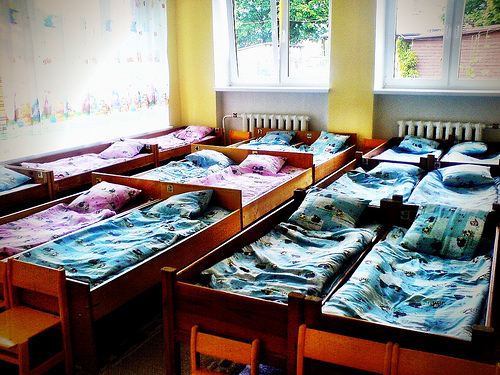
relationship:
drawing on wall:
[13, 99, 41, 130] [1, 1, 172, 163]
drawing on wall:
[41, 13, 58, 29] [1, 1, 172, 163]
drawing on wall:
[142, 88, 169, 109] [1, 1, 172, 163]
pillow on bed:
[172, 124, 216, 141] [130, 124, 224, 166]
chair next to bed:
[1, 256, 75, 375] [1, 181, 242, 371]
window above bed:
[221, 1, 330, 89] [130, 124, 224, 166]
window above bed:
[221, 1, 330, 89] [191, 127, 300, 159]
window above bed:
[384, 2, 500, 94] [353, 134, 455, 165]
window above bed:
[384, 2, 500, 94] [431, 136, 500, 171]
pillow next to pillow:
[66, 178, 144, 212] [150, 188, 215, 220]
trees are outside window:
[234, 0, 329, 43] [221, 1, 330, 89]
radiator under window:
[221, 113, 313, 142] [221, 1, 330, 89]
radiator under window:
[394, 119, 500, 146] [384, 2, 500, 94]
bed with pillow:
[1, 181, 242, 371] [150, 188, 215, 220]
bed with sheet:
[1, 181, 242, 371] [13, 207, 214, 286]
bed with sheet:
[159, 188, 389, 364] [191, 220, 375, 305]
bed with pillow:
[159, 188, 389, 364] [285, 184, 373, 231]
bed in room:
[130, 124, 224, 166] [2, 4, 500, 370]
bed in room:
[191, 127, 300, 159] [2, 4, 500, 370]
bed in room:
[353, 134, 455, 165] [2, 4, 500, 370]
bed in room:
[431, 136, 500, 171] [2, 4, 500, 370]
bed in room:
[1, 181, 242, 371] [2, 4, 500, 370]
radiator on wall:
[221, 113, 313, 142] [165, 0, 377, 143]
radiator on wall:
[394, 119, 500, 146] [372, 87, 499, 154]